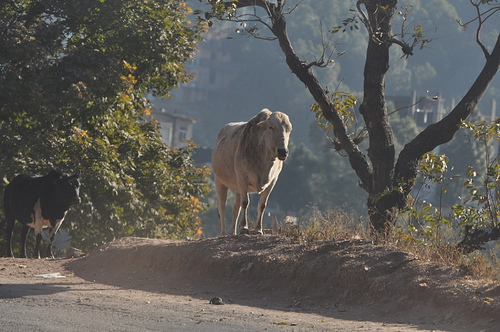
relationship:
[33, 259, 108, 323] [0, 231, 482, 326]
dirt on ground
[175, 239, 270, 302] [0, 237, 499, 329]
dirt on ground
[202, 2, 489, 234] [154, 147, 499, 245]
trees on hill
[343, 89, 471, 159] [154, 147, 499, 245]
house on hill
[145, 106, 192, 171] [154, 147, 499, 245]
house on hill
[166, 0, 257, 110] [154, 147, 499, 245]
house on hill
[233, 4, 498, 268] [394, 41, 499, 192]
tree has branch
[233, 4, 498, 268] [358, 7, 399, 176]
tree has branch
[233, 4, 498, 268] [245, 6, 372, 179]
tree has branch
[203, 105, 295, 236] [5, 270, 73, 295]
cow casting shadow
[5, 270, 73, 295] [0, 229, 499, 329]
shadow on dirt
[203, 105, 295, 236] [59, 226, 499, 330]
cow standing on hill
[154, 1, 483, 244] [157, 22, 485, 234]
haze over mountain side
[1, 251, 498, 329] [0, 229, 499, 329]
road made of dirt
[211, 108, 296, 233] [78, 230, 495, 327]
cow standing on hill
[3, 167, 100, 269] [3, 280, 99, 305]
cow casting shadow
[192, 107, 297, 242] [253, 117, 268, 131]
cow has ear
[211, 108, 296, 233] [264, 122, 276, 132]
cow has eye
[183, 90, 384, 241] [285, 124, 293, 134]
cow has eye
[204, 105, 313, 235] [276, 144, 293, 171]
cow has nose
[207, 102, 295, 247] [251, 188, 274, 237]
cow has leg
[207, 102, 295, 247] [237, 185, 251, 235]
cow has right leg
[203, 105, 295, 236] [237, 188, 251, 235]
cow has leg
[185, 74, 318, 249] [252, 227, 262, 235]
cow has hoof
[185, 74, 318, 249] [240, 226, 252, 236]
cow has hoof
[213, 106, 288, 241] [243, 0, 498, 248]
cow next to tree